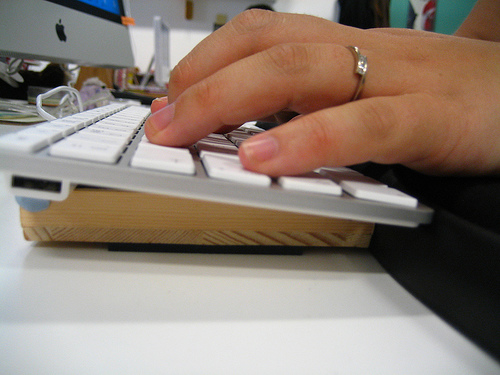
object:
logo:
[55, 19, 67, 43]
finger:
[145, 43, 397, 146]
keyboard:
[0, 103, 434, 247]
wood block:
[20, 189, 374, 247]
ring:
[346, 46, 369, 102]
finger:
[239, 94, 409, 177]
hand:
[144, 0, 498, 177]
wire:
[36, 64, 83, 121]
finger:
[151, 96, 168, 115]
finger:
[168, 9, 367, 104]